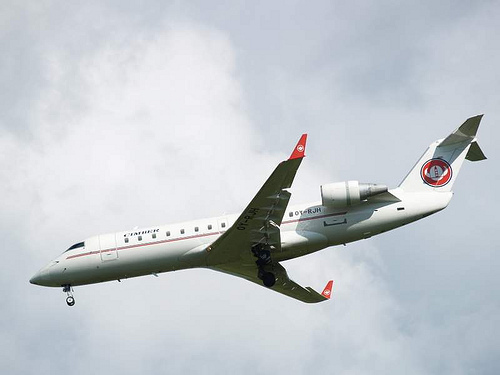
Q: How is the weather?
A: It is cloudy.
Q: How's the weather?
A: It is cloudy.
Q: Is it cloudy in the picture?
A: Yes, it is cloudy.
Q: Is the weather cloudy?
A: Yes, it is cloudy.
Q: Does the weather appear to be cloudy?
A: Yes, it is cloudy.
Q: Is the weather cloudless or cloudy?
A: It is cloudy.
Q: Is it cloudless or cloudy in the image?
A: It is cloudy.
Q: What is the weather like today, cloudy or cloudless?
A: It is cloudy.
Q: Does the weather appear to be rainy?
A: No, it is cloudy.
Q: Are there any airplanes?
A: Yes, there is an airplane.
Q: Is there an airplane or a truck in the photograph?
A: Yes, there is an airplane.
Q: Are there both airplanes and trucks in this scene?
A: No, there is an airplane but no trucks.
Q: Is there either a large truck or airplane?
A: Yes, there is a large airplane.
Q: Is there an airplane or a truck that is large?
A: Yes, the airplane is large.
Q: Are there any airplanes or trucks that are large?
A: Yes, the airplane is large.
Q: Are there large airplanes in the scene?
A: Yes, there is a large airplane.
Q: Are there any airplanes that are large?
A: Yes, there is an airplane that is large.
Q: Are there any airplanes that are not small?
A: Yes, there is a large airplane.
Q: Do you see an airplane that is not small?
A: Yes, there is a large airplane.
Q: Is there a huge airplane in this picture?
A: Yes, there is a huge airplane.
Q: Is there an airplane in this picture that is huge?
A: Yes, there is an airplane that is huge.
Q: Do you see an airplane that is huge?
A: Yes, there is an airplane that is huge.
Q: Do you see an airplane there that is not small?
A: Yes, there is a huge airplane.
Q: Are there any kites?
A: No, there are no kites.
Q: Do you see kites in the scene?
A: No, there are no kites.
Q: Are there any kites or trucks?
A: No, there are no kites or trucks.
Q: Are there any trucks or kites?
A: No, there are no kites or trucks.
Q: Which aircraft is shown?
A: The aircraft is an airplane.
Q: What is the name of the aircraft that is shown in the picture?
A: The aircraft is an airplane.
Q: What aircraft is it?
A: The aircraft is an airplane.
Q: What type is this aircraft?
A: This is an airplane.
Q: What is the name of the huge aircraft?
A: The aircraft is an airplane.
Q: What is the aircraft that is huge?
A: The aircraft is an airplane.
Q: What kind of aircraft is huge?
A: The aircraft is an airplane.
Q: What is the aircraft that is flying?
A: The aircraft is an airplane.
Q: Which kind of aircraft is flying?
A: The aircraft is an airplane.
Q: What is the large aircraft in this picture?
A: The aircraft is an airplane.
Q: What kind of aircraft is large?
A: The aircraft is an airplane.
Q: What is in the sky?
A: The plane is in the sky.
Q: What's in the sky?
A: The plane is in the sky.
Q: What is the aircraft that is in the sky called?
A: The aircraft is an airplane.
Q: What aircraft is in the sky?
A: The aircraft is an airplane.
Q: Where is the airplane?
A: The airplane is in the sky.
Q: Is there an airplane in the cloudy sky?
A: Yes, there is an airplane in the sky.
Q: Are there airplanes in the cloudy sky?
A: Yes, there is an airplane in the sky.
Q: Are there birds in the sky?
A: No, there is an airplane in the sky.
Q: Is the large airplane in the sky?
A: Yes, the airplane is in the sky.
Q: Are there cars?
A: No, there are no cars.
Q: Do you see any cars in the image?
A: No, there are no cars.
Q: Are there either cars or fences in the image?
A: No, there are no cars or fences.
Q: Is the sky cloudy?
A: Yes, the sky is cloudy.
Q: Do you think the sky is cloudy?
A: Yes, the sky is cloudy.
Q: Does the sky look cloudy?
A: Yes, the sky is cloudy.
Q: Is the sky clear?
A: No, the sky is cloudy.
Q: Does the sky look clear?
A: No, the sky is cloudy.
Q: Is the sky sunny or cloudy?
A: The sky is cloudy.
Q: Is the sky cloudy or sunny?
A: The sky is cloudy.